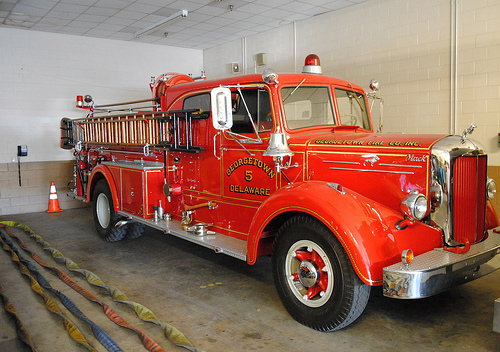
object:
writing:
[225, 157, 276, 197]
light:
[400, 190, 428, 220]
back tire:
[91, 179, 129, 242]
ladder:
[74, 118, 196, 149]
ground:
[12, 219, 252, 330]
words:
[357, 140, 364, 144]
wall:
[202, 34, 499, 157]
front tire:
[269, 214, 371, 336]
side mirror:
[210, 86, 234, 130]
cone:
[45, 181, 63, 213]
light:
[305, 54, 321, 66]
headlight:
[486, 178, 497, 200]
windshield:
[280, 84, 368, 129]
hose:
[2, 245, 92, 351]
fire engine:
[154, 102, 364, 186]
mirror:
[378, 101, 383, 130]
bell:
[263, 132, 296, 173]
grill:
[450, 151, 488, 245]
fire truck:
[57, 54, 500, 335]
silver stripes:
[49, 192, 57, 195]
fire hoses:
[12, 219, 165, 328]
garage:
[9, 12, 499, 351]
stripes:
[305, 141, 428, 156]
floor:
[0, 211, 500, 351]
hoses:
[0, 298, 41, 351]